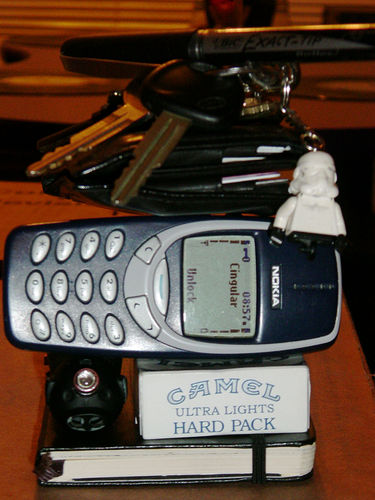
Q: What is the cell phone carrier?
A: Cingular.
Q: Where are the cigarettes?
A: Under the cell phone.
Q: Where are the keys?
A: On top of the wallet.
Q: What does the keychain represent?
A: Star Wars.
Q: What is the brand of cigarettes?
A: Camel.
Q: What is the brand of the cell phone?
A: Nokia.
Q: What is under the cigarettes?
A: A black book.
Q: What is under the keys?
A: A wallet.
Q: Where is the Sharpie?
A: On the keys.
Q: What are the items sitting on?
A: A table.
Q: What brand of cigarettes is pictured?
A: Camel.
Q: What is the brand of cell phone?
A: Nokia.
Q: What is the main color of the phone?
A: Blue.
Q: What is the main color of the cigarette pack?
A: White.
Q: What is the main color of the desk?
A: Brown.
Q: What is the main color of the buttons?
A: Grey.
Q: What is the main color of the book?
A: Black.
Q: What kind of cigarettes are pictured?
A: Ultra light.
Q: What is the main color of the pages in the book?
A: White.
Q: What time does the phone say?
A: 8:57.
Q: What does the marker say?
A: Exact-Tip.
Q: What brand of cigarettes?
A: Camel.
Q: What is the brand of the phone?
A: Nokia.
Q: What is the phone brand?
A: Cingular.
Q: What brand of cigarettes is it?
A: Camel.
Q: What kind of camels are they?
A: Ultra light.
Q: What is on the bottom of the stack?
A: A notebook.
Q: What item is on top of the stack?
A: A pen.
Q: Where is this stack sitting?
A: On a table.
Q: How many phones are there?
A: 1.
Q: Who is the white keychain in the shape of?
A: Darth vader.